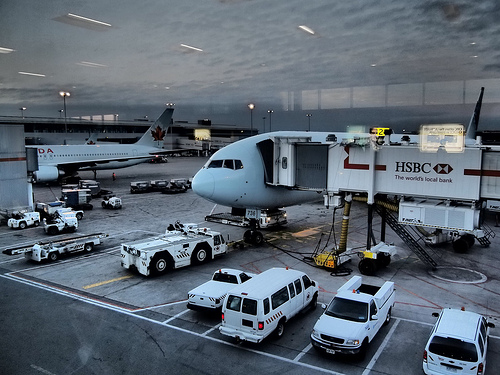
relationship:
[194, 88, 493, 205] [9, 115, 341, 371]
plane at airport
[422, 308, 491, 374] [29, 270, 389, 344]
cars parked in row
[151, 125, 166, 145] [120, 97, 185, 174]
leaf on tail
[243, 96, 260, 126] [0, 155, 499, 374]
lights on ground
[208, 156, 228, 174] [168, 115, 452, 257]
window on plane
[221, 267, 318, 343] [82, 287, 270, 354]
commercial van on ground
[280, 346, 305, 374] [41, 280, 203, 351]
lines on ground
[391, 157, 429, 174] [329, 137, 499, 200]
letters on terminal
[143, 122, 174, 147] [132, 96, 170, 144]
leaf on tail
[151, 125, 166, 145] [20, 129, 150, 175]
leaf on airplane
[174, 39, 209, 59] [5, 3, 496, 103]
tube light on ceiling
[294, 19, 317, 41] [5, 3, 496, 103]
tube light on ceiling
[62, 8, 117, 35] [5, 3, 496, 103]
tube light on ceiling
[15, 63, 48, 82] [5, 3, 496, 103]
tube light on ceiling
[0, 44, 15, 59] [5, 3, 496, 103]
tube light on ceiling